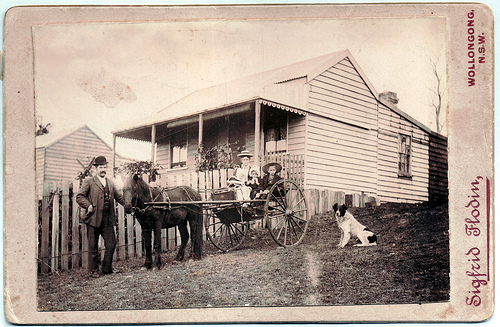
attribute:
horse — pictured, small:
[121, 169, 205, 270]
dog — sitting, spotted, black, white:
[333, 201, 378, 247]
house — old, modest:
[114, 46, 449, 218]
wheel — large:
[264, 178, 311, 247]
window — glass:
[265, 112, 287, 154]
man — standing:
[76, 155, 134, 278]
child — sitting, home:
[252, 162, 285, 208]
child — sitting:
[246, 165, 261, 198]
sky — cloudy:
[36, 22, 456, 156]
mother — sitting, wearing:
[228, 150, 253, 206]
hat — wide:
[262, 158, 282, 173]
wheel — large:
[204, 187, 250, 250]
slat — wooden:
[378, 122, 428, 138]